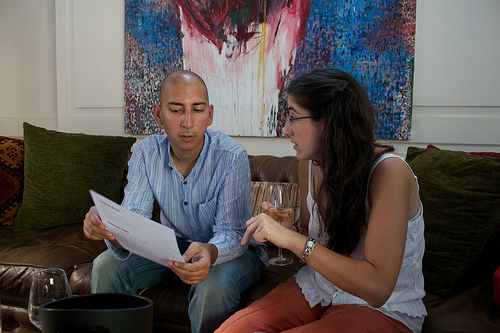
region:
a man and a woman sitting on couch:
[74, 60, 434, 331]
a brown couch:
[0, 148, 496, 331]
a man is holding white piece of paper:
[71, 60, 268, 330]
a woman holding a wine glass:
[210, 65, 430, 330]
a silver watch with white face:
[298, 230, 320, 263]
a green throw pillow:
[10, 117, 135, 240]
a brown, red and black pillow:
[0, 130, 29, 236]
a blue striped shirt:
[102, 124, 254, 272]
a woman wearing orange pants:
[209, 272, 429, 332]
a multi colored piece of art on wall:
[110, 1, 417, 148]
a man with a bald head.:
[144, 51, 242, 171]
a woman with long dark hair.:
[258, 62, 395, 279]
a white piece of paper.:
[81, 179, 205, 282]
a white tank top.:
[258, 158, 438, 325]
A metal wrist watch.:
[296, 225, 327, 270]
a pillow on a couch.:
[181, 153, 327, 293]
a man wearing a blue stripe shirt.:
[91, 123, 257, 264]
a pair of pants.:
[210, 268, 404, 330]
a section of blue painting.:
[276, 0, 421, 145]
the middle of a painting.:
[199, 70, 270, 128]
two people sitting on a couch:
[2, 70, 499, 332]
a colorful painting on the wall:
[121, 0, 418, 145]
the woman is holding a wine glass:
[213, 67, 430, 332]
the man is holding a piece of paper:
[83, 68, 261, 331]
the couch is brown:
[0, 118, 499, 331]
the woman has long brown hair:
[281, 67, 377, 257]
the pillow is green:
[14, 118, 134, 230]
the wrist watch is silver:
[297, 231, 317, 263]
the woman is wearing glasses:
[280, 65, 379, 165]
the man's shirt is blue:
[103, 133, 255, 289]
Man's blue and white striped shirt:
[111, 132, 270, 276]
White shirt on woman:
[282, 152, 441, 327]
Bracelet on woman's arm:
[296, 232, 323, 268]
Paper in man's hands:
[80, 184, 201, 284]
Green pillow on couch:
[11, 116, 153, 241]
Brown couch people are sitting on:
[3, 223, 103, 331]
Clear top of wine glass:
[21, 265, 81, 330]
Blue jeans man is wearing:
[79, 228, 271, 331]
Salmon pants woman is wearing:
[205, 274, 414, 331]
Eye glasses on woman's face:
[276, 109, 338, 129]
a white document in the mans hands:
[89, 188, 185, 273]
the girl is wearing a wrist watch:
[299, 236, 317, 263]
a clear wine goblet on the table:
[28, 266, 70, 330]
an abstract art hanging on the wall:
[125, 0, 416, 70]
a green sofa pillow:
[15, 120, 80, 231]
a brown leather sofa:
[1, 233, 88, 295]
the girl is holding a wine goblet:
[263, 180, 293, 267]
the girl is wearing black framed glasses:
[283, 113, 313, 123]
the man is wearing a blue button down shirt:
[122, 128, 251, 214]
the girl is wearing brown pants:
[214, 281, 412, 331]